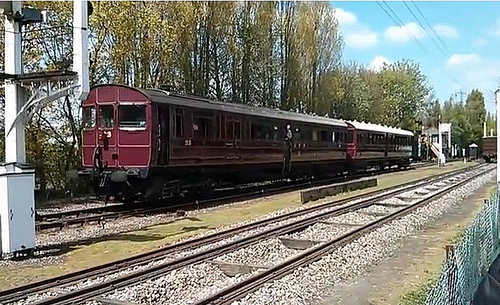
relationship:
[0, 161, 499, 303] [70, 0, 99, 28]
rail has light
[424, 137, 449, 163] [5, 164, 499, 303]
strairway near track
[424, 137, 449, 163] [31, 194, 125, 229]
strairway near track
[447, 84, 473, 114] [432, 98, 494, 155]
ferris wheel over trees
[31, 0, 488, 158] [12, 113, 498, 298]
trees near train bed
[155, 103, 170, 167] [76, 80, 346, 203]
entry door into car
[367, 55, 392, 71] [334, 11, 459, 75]
cloud are in sky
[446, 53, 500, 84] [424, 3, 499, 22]
cloud in blue sky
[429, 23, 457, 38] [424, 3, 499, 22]
cloud in blue sky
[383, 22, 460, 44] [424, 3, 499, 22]
cloud in blue sky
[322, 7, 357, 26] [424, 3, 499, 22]
cloud in blue sky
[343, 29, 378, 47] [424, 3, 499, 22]
cloud in blue sky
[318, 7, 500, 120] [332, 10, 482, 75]
clouds are in sky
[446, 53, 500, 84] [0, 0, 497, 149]
cloud in sky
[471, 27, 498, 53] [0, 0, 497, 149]
cloud in sky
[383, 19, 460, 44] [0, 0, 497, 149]
cloud in sky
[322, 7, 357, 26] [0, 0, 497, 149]
cloud in sky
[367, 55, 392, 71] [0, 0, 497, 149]
cloud in sky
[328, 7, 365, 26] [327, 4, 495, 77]
cloud in sky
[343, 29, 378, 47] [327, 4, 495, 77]
cloud in sky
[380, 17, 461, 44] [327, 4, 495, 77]
cloud in sky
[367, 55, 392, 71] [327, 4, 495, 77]
cloud in sky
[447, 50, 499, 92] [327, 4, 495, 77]
cloud in sky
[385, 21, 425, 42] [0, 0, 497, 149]
cloud in sky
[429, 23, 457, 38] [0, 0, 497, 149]
cloud in sky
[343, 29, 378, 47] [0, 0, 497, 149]
cloud in sky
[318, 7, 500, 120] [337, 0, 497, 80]
clouds are in sky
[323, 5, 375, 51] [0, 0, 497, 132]
cloud in sky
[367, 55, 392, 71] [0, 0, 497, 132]
cloud in sky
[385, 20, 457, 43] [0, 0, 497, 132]
cloud in sky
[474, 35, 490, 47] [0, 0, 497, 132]
cloud in sky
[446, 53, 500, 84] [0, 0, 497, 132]
cloud in sky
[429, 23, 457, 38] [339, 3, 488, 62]
cloud are in sky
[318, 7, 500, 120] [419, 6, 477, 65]
clouds are in sky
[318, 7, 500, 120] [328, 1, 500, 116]
clouds are in blue sky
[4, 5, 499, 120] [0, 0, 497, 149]
clouds are in sky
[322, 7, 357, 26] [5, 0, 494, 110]
cloud are in sky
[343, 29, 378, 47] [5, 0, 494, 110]
cloud are in sky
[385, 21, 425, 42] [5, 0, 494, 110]
cloud are in sky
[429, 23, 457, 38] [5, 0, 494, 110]
cloud are in sky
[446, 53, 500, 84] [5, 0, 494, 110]
cloud are in sky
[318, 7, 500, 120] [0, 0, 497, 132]
clouds are in sky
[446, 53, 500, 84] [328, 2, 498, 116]
cloud in blue sky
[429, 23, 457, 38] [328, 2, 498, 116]
cloud in blue sky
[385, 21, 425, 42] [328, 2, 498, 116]
cloud in blue sky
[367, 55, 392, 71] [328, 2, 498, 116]
cloud in blue sky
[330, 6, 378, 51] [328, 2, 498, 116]
cloud in blue sky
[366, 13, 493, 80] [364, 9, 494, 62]
clouds are in sky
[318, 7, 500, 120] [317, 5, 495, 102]
clouds are in sky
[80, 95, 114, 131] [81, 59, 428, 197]
window in train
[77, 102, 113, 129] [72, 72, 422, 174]
window in train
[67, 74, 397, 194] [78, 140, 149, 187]
train in coupling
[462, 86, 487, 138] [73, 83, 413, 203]
tree in train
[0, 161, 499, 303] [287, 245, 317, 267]
rail with rail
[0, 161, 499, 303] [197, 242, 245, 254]
rail with rail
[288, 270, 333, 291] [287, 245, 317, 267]
stones along rail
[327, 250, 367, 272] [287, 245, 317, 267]
stones along rail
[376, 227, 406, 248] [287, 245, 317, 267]
stones along rail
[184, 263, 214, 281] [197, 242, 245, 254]
stones along rail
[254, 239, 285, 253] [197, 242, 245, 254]
stones along rail